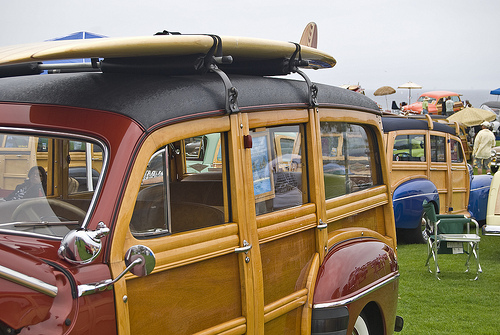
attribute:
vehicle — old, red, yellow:
[7, 75, 396, 330]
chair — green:
[424, 203, 483, 280]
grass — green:
[403, 245, 499, 331]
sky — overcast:
[7, 4, 495, 94]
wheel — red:
[354, 312, 373, 334]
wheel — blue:
[423, 206, 433, 238]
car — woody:
[59, 54, 435, 323]